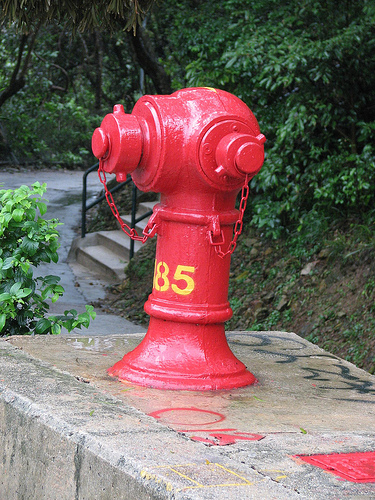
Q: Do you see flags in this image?
A: No, there are no flags.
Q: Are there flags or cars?
A: No, there are no flags or cars.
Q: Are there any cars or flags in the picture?
A: No, there are no flags or cars.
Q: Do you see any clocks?
A: No, there are no clocks.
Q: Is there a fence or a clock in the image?
A: No, there are no clocks or fences.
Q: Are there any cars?
A: No, there are no cars.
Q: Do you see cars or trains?
A: No, there are no cars or trains.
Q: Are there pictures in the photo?
A: No, there are no pictures.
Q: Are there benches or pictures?
A: No, there are no pictures or benches.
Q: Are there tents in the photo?
A: No, there are no tents.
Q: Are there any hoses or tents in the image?
A: No, there are no tents or hoses.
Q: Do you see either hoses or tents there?
A: No, there are no tents or hoses.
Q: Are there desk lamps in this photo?
A: No, there are no desk lamps.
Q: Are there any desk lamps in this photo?
A: No, there are no desk lamps.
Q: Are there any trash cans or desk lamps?
A: No, there are no desk lamps or trash cans.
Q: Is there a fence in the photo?
A: No, there are no fences.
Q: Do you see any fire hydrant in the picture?
A: Yes, there is a fire hydrant.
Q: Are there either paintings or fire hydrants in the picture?
A: Yes, there is a fire hydrant.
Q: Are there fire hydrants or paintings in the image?
A: Yes, there is a fire hydrant.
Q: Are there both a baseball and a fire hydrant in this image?
A: No, there is a fire hydrant but no baseballs.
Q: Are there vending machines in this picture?
A: No, there are no vending machines.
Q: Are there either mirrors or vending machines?
A: No, there are no vending machines or mirrors.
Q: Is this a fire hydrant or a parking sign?
A: This is a fire hydrant.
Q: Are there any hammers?
A: No, there are no hammers.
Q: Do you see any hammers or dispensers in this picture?
A: No, there are no hammers or dispensers.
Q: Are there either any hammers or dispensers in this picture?
A: No, there are no hammers or dispensers.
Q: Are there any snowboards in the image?
A: No, there are no snowboards.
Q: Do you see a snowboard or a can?
A: No, there are no snowboards or cans.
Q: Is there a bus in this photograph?
A: No, there are no buses.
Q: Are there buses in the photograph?
A: No, there are no buses.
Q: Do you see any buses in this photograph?
A: No, there are no buses.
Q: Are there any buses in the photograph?
A: No, there are no buses.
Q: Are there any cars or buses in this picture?
A: No, there are no buses or cars.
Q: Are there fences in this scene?
A: No, there are no fences.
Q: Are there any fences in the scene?
A: No, there are no fences.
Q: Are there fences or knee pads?
A: No, there are no fences or knee pads.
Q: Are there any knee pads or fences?
A: No, there are no fences or knee pads.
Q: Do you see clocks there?
A: No, there are no clocks.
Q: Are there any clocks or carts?
A: No, there are no clocks or carts.